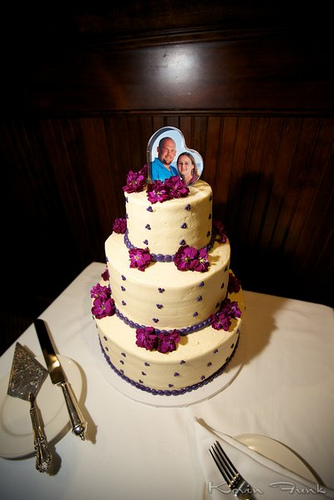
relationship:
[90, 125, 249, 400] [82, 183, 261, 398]
cake has tiers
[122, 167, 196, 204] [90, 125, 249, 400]
flowers on cake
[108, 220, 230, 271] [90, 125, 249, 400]
flowers on cake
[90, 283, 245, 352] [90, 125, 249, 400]
flowers on cake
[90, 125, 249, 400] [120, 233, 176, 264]
cake has trim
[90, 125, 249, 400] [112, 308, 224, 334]
cake has trim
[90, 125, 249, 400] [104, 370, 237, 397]
cake has trim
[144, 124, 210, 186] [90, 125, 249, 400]
heart on top of cake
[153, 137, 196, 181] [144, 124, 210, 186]
photo inside heart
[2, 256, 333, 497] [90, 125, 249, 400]
table cloth under cake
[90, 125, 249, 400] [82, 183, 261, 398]
cake has layers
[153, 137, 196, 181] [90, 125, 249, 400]
picture on top of cake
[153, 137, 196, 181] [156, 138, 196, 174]
picture of couple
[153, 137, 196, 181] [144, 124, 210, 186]
photo shaped like heart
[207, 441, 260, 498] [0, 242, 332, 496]
fork on table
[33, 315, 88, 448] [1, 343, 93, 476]
knife over dish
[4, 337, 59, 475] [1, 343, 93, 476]
spatula over dish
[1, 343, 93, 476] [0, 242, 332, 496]
dish on top of table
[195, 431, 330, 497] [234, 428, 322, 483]
napkin over dish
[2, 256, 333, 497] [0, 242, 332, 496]
table cloth on top of table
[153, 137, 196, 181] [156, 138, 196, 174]
photo of couple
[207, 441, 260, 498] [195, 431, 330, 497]
fork on napkin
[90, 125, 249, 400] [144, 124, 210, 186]
cake has decoration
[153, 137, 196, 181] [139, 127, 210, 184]
photo in frame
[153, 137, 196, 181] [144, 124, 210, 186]
photo on heart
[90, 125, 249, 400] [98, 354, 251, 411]
cake on top of plate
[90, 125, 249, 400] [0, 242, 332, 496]
cake on top of table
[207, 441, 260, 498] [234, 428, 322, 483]
fork on plate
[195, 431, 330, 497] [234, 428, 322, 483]
napkin on plate